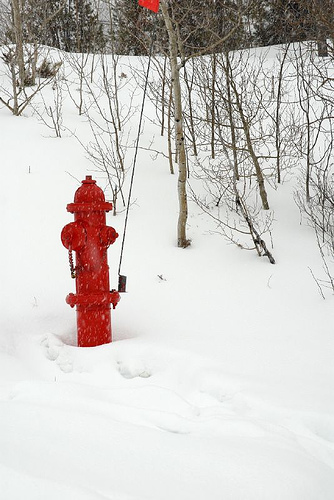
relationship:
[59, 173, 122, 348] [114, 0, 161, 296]
fire hydrant with flag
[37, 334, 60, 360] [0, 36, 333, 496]
footprint in snow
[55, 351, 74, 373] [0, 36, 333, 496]
footprint in snow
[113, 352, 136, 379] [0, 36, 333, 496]
footprint in snow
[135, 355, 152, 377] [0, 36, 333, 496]
footprint in snow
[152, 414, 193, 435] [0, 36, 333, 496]
footprint in snow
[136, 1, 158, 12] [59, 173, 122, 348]
flag on fire hydrant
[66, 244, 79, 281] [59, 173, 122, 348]
chain on fire hydrant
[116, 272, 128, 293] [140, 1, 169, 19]
spring at base of flag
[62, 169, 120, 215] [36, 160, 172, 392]
cap of hydrant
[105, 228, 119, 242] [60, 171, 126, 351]
cap of hydrant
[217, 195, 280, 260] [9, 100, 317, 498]
branch snow in snow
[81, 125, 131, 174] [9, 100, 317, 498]
branch snow in snow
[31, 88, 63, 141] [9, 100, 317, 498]
branch snow in snow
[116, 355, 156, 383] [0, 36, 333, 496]
prints in snow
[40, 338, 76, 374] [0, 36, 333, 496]
footprints in snow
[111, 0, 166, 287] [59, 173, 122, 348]
red flag on fire hydrant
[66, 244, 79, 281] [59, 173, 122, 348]
chain hanging from fire hydrant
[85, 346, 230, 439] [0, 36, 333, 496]
prints in snow